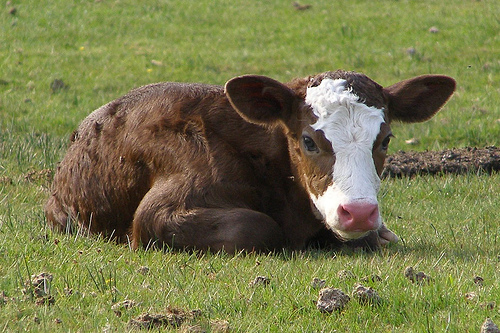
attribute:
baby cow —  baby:
[42, 68, 459, 257]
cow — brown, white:
[70, 64, 415, 263]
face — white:
[289, 70, 392, 242]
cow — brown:
[35, 62, 466, 283]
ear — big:
[387, 69, 457, 130]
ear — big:
[221, 66, 297, 133]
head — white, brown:
[223, 62, 462, 243]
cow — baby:
[119, 60, 467, 241]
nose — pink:
[338, 201, 380, 233]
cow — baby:
[40, 37, 497, 302]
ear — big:
[221, 70, 292, 132]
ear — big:
[385, 70, 455, 125]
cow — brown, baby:
[48, 77, 459, 255]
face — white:
[246, 30, 434, 242]